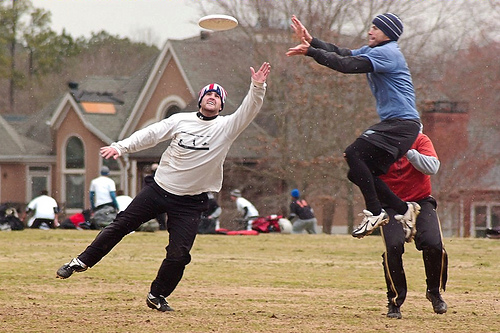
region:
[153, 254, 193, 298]
man is wearing black pants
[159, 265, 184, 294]
man is wearing black pants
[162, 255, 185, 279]
man is wearing black pants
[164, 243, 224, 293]
man is wearing black pants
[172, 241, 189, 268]
man is wearing black pants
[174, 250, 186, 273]
man is wearing black pants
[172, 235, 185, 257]
man is wearing black pants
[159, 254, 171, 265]
man is wearing black pants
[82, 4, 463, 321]
three men playing disk game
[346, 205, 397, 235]
the white colored shoe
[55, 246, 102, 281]
the black colored shoe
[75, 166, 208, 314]
the black colored trousers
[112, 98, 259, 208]
the white colored t shirt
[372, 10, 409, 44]
the black colored cap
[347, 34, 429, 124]
the blue colored t shirt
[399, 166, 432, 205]
the red colored t shirt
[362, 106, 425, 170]
the black cored shorts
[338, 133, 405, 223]
the black colored socks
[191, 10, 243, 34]
Small white frisbee in game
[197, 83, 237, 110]
Man wearing red, blue, and white hat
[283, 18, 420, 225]
Man jumps to catch frisbee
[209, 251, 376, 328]
Grass is short and brown-green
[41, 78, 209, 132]
New England style house in background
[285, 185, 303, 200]
Person wearing blue hat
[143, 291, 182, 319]
Man in white shirt is wearing cleats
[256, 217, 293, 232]
Red back between people in background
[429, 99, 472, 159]
Red brick chimney on building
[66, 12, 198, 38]
Sky is gray and cloudy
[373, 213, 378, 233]
THE CHECK IS BLACK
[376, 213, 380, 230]
THE CHECK IS BLACK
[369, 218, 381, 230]
THE CHECK IS BLACK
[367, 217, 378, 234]
THE CHECK IS BLACK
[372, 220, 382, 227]
THE CHECK IS BLACK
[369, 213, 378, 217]
THE CHECK IS BLACK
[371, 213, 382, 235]
THE CHECK IS BLACK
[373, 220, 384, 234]
THE CHECK IS BLACK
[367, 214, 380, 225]
THE CHECK IS BLACK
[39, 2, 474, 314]
men playing frisbee in a park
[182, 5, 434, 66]
man about to catch a frisbee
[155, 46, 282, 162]
man trying to intercept a frisbee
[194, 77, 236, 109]
a white, red and blue wool hat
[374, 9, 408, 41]
a blue wool hat with white lines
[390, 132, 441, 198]
red T-shirt over a white long sleeve shirt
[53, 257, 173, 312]
man wearing black shoes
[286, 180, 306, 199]
a blue hat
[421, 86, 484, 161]
a brick chimney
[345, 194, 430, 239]
man wearing white sneakers